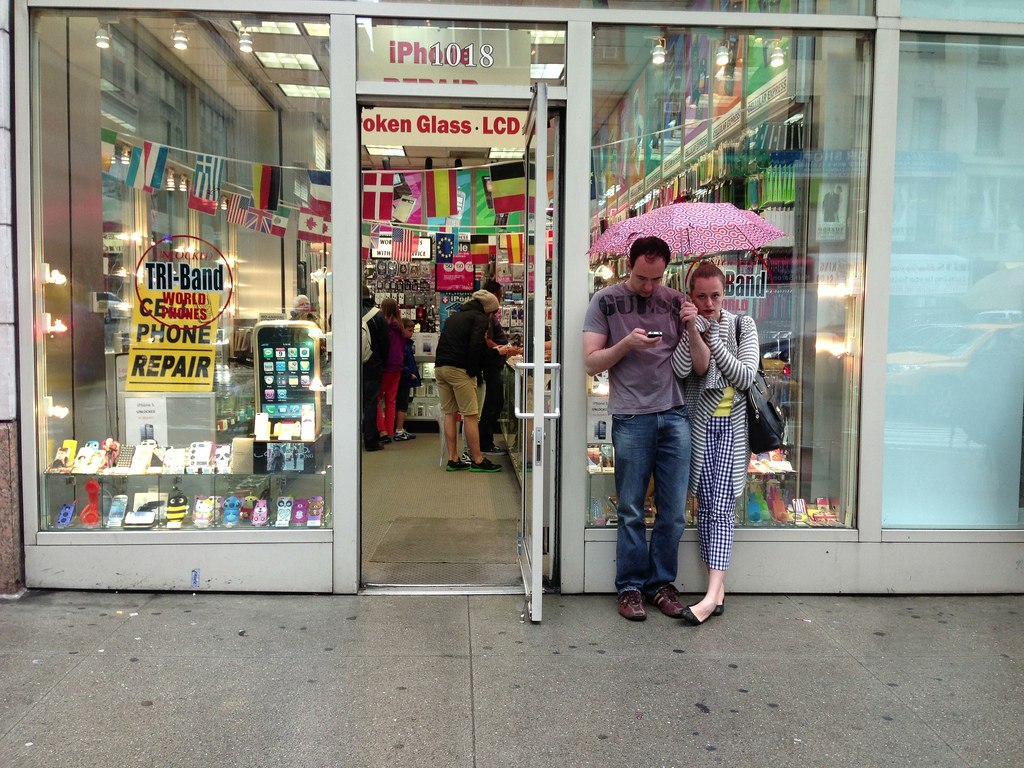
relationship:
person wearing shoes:
[433, 289, 504, 479] [440, 456, 508, 475]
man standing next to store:
[577, 238, 691, 622] [10, 1, 1022, 587]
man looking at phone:
[577, 238, 691, 622] [643, 324, 666, 340]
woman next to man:
[672, 270, 762, 626] [577, 238, 691, 622]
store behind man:
[10, 1, 1022, 587] [577, 238, 691, 622]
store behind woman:
[10, 1, 1022, 587] [672, 270, 762, 626]